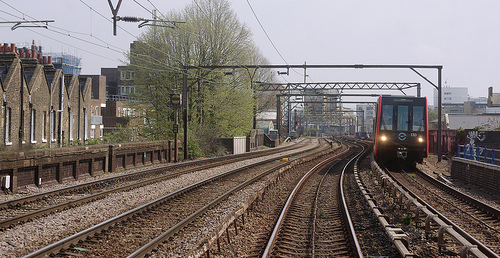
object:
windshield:
[376, 99, 429, 135]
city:
[278, 87, 500, 137]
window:
[390, 96, 416, 106]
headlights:
[379, 135, 387, 141]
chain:
[369, 87, 434, 174]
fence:
[0, 140, 180, 193]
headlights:
[418, 137, 424, 142]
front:
[375, 94, 429, 163]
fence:
[457, 143, 499, 166]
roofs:
[0, 55, 15, 88]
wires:
[244, 0, 289, 65]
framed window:
[31, 108, 38, 143]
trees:
[241, 54, 282, 130]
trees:
[203, 7, 255, 135]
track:
[412, 165, 500, 213]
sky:
[0, 0, 499, 103]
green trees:
[117, 0, 255, 145]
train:
[373, 94, 429, 164]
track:
[340, 142, 367, 258]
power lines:
[79, 0, 237, 73]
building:
[43, 56, 69, 148]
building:
[0, 43, 32, 149]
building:
[68, 74, 84, 146]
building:
[81, 74, 105, 143]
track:
[380, 161, 500, 258]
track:
[0, 138, 311, 228]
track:
[125, 138, 333, 257]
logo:
[397, 132, 407, 141]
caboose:
[180, 64, 442, 162]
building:
[17, 47, 52, 146]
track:
[262, 138, 351, 257]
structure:
[256, 81, 419, 90]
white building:
[431, 80, 483, 107]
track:
[0, 136, 306, 206]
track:
[20, 138, 321, 258]